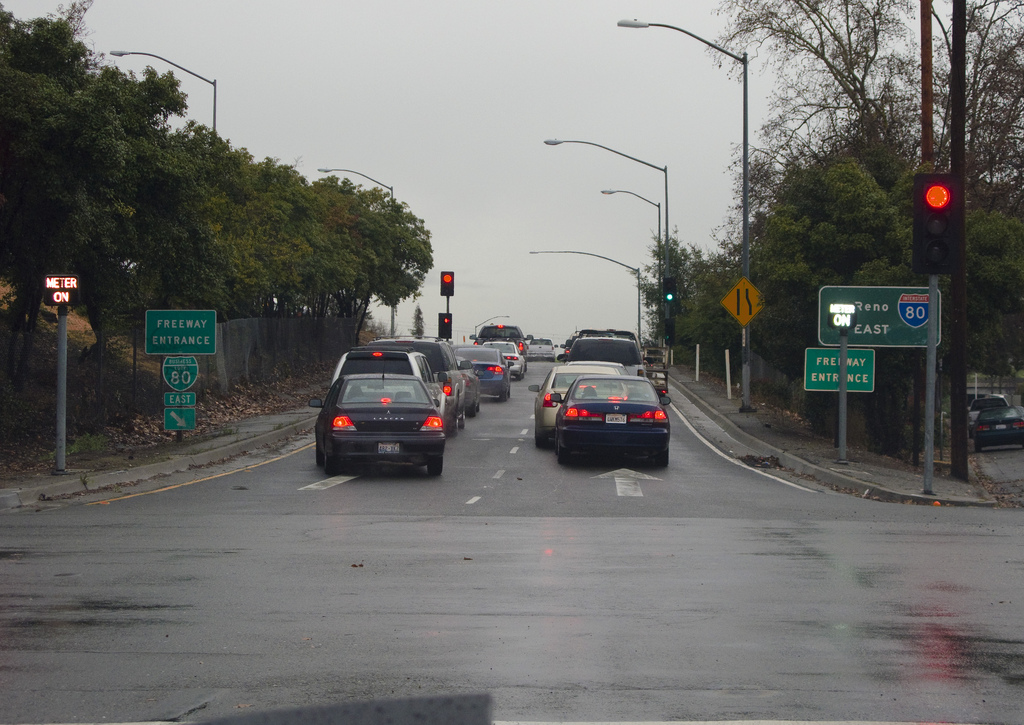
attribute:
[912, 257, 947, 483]
pole — metal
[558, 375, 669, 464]
car — metal, small, blue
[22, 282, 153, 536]
pole — short, round, metal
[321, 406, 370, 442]
red light — small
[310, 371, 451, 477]
car — dark, small, black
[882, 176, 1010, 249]
street light — large, red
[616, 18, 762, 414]
light — tall, large, metal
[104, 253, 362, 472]
fence — long, metal, grey